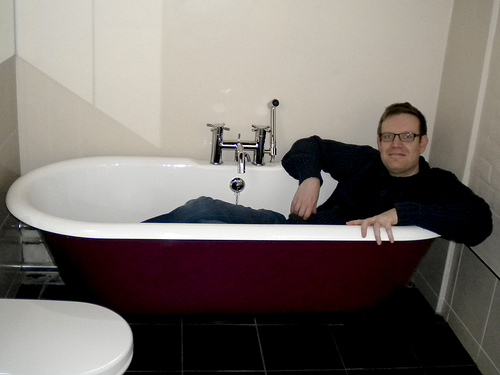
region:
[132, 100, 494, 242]
a man lounging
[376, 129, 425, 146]
a pair of black framed glasses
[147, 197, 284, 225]
a knee covered up with blue jean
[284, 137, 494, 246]
a long sleeve black shirt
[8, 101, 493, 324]
a guy laying down in bathtub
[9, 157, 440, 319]
a bathtub with red exterior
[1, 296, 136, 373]
white lid of a toilet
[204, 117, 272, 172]
silver mounted bathtub faucets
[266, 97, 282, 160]
a slim design shower head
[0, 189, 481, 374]
black square tile on floor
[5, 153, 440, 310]
a white and red bathtub in a bathroom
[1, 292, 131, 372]
white cover seat of a toilet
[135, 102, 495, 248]
a man laying in a bathtub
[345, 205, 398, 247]
man holding the side of a bathtub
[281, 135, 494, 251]
man wearing a black sweater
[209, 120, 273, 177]
a silver faucet on a bathtub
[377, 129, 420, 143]
man wearing brown glasses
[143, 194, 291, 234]
man wearing blue jeans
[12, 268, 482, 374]
black tiles on a bathroom floor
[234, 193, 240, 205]
a silver chain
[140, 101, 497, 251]
A man stretched out in a bathtub.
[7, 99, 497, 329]
A man with clothes on inside of an empty bathtub.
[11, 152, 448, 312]
A red and white bathtub.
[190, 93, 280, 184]
Silver bathroom fixtures.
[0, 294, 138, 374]
A white toilet.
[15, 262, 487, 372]
A black tile floor.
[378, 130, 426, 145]
A pair of black framed glasses.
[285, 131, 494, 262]
A long sleeve black shirt.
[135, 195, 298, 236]
A pair of blue jeans.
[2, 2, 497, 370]
White walls in a bathroom.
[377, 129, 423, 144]
eye glasses on a man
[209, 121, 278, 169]
stainless steel tub faucet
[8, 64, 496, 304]
man in a bath tub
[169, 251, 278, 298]
maroon bottom of a bath tub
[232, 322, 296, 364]
black tile floor in a bathroom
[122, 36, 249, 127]
shadow cast ona white wall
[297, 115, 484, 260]
black shirt on a man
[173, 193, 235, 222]
blue jeans on a man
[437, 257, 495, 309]
tan tile lining the bathroom wall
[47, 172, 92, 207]
white interior of a bath tub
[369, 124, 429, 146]
the man is wearing glasses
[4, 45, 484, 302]
a man is lying in a tub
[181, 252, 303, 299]
the tub is red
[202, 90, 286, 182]
the faucet is silver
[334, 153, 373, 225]
the shirt is black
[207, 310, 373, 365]
the floor is black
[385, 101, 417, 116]
the man has hair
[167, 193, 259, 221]
the man is wearing jeans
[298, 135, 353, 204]
the shirt is long sleeved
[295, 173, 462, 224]
the man is wearing a shirt